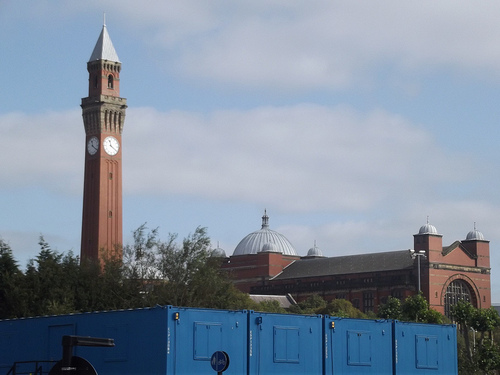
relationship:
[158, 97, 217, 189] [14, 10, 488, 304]
white clouds in sky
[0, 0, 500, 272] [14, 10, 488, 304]
cloud in sky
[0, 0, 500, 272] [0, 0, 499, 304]
cloud are in blue sky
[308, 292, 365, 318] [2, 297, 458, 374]
tree behind trailers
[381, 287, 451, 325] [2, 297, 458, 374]
tree behind trailers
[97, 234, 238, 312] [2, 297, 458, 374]
tree behind trailers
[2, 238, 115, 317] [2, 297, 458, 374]
tree behind trailers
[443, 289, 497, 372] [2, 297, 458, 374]
tree behind trailers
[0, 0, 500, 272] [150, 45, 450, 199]
cloud in sky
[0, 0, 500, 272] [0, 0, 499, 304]
cloud in blue sky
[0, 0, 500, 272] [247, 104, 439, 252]
cloud in sky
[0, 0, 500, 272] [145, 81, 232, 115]
cloud in sky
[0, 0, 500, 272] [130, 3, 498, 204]
cloud in sky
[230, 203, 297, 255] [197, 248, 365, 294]
round top on top of building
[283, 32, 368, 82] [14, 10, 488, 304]
cloud in sky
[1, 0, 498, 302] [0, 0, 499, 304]
white clouds in blue sky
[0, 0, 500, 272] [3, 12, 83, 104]
cloud in blue sky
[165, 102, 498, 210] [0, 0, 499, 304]
white louds in blue sky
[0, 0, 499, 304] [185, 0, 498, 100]
blue sky with white clouds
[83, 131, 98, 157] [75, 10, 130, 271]
clock on tower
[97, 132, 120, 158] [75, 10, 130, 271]
clock on tower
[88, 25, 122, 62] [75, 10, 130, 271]
pyramid shape on top of tower